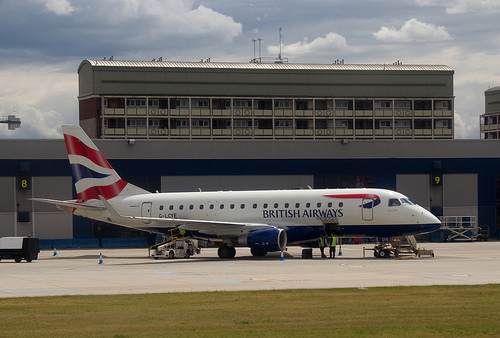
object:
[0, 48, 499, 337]
airport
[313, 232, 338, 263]
men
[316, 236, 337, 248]
vest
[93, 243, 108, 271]
cone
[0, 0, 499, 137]
sky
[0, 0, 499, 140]
clouds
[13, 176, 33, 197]
number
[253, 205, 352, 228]
text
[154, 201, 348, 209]
windows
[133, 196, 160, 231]
door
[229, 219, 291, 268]
engine